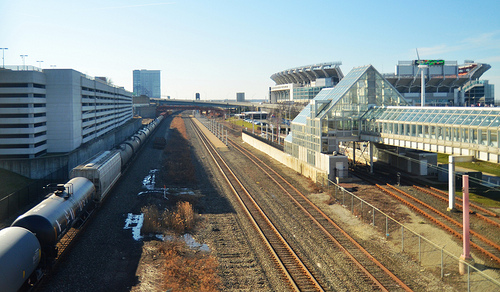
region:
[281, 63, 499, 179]
A new glass enclosed monorail terminal.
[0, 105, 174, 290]
A freight train made up mostly of tanker cars.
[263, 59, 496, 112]
A quite large sports stadium open to the sky.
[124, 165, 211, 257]
Pools of standing water between the tracks.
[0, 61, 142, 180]
A nondesript building next to the railroad tracks.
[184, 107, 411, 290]
Two parallel tracks leading off into the distance.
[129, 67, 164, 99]
A tall office building in the middle distance.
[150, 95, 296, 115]
A roadway bridge over the railroad tracks.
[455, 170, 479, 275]
A pink pole with no discernable purpose.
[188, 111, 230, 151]
A passenger platform with many lamp posts.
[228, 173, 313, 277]
A set of train tracks.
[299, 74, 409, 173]
A glass building.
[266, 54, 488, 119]
A sports stadium.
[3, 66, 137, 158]
A multi level parking lot.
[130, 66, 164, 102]
A tall building.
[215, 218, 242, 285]
Dirt covered ground.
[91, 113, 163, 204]
Several cars on a freight train.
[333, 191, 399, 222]
Chain linked fencing.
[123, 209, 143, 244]
A puddle of water.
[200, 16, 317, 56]
The clear sky.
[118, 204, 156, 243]
a puddle of water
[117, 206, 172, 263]
a puddle of water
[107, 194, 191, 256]
a puddle of water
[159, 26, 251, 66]
the sky is clear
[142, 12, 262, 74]
the sky is clear